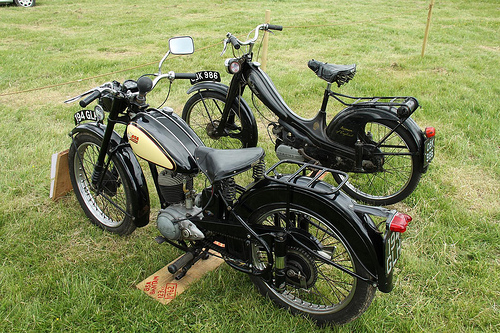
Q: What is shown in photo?
A: Bikes.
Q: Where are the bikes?
A: Yard.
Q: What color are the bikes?
A: Black.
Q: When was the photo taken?
A: Morning.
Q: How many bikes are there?
A: Two.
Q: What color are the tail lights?
A: Red.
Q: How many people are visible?
A: Zero.